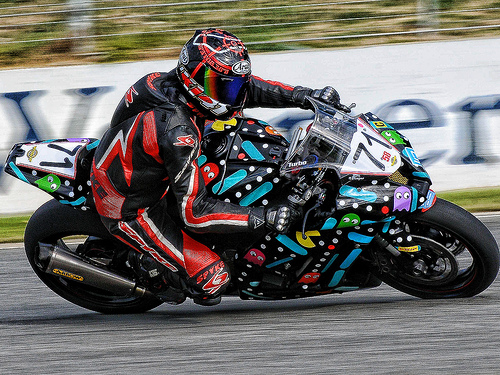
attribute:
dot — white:
[232, 190, 242, 201]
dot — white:
[323, 248, 331, 260]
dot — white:
[365, 205, 373, 211]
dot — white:
[256, 125, 263, 134]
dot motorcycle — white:
[373, 188, 395, 205]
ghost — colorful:
[335, 211, 360, 230]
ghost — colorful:
[388, 185, 410, 214]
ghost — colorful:
[296, 270, 321, 285]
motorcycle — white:
[23, 70, 483, 315]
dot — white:
[319, 257, 327, 264]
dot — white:
[28, 168, 38, 175]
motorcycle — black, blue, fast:
[11, 90, 498, 322]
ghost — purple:
[387, 187, 413, 213]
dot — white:
[314, 260, 325, 271]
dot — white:
[330, 233, 342, 245]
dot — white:
[253, 175, 262, 181]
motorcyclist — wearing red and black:
[85, 26, 344, 307]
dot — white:
[364, 203, 374, 215]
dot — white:
[353, 201, 366, 209]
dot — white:
[416, 195, 427, 203]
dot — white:
[367, 176, 380, 187]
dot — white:
[384, 181, 399, 190]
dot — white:
[233, 190, 243, 199]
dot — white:
[381, 180, 392, 190]